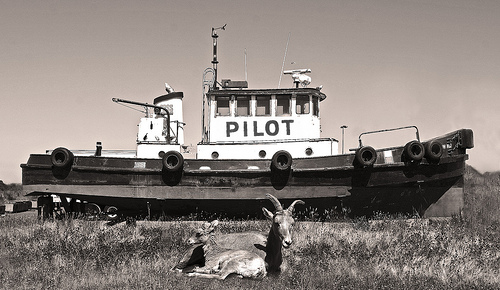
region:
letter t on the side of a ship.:
[279, 119, 300, 136]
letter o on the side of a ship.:
[266, 116, 280, 139]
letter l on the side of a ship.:
[249, 119, 263, 136]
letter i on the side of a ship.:
[235, 121, 251, 143]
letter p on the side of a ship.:
[224, 117, 238, 147]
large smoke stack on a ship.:
[109, 77, 186, 171]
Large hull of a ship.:
[18, 126, 475, 228]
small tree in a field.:
[251, 194, 296, 287]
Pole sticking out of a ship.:
[203, 13, 231, 90]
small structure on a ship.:
[194, 89, 348, 170]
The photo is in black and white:
[22, 29, 449, 279]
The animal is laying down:
[142, 208, 326, 288]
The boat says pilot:
[150, 72, 325, 189]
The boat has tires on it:
[39, 142, 499, 174]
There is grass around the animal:
[60, 237, 348, 284]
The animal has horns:
[250, 186, 374, 260]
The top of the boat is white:
[148, 54, 350, 174]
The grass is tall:
[317, 213, 435, 281]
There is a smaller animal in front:
[160, 217, 280, 281]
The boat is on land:
[9, 145, 461, 284]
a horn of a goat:
[266, 189, 287, 214]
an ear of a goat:
[259, 203, 276, 221]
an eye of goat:
[286, 219, 301, 229]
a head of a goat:
[259, 199, 306, 251]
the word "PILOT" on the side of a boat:
[221, 119, 303, 142]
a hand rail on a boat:
[356, 122, 420, 144]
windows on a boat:
[214, 88, 314, 117]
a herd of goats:
[173, 189, 299, 289]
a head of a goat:
[180, 216, 222, 249]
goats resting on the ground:
[174, 211, 313, 283]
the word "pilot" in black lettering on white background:
[211, 116, 311, 137]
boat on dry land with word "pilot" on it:
[19, 19, 479, 195]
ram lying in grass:
[163, 194, 313, 283]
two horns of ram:
[263, 189, 310, 213]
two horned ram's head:
[257, 188, 310, 254]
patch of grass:
[331, 239, 463, 281]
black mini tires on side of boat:
[41, 146, 188, 183]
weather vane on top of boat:
[201, 18, 231, 70]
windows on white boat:
[208, 92, 315, 119]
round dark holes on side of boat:
[203, 146, 269, 160]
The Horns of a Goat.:
[258, 190, 316, 213]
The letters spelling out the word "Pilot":
[214, 116, 306, 140]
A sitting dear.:
[176, 226, 265, 281]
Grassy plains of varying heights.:
[309, 220, 499, 289]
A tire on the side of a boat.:
[158, 150, 186, 173]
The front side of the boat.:
[355, 122, 485, 219]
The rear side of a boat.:
[22, 145, 133, 228]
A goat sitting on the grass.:
[252, 195, 306, 285]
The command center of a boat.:
[197, 75, 330, 158]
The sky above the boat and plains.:
[1, 2, 499, 87]